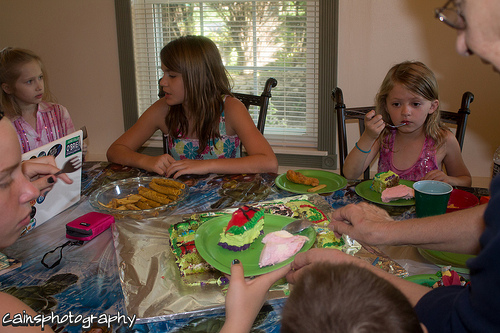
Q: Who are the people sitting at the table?
A: Young children.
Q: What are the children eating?
A: Cake.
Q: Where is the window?
A: Behind a girl with long hair.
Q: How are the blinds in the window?
A: Open.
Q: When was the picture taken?
A: During the daytime.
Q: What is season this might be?
A: Summer.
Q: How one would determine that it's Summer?
A: By the way the children are dressed.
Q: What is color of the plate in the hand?
A: Green.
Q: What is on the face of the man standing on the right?
A: Glasses.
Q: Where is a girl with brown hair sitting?
A: In front of window.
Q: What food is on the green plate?
A: Cake.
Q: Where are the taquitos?
A: Clear plate.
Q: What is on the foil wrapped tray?
A: Cake.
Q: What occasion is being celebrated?
A: Birthday.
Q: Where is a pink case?
A: On table in front of computer.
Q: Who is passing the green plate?
A: Girl with blue nail polish.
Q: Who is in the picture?
A: A man and children.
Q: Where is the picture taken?
A: A dining room.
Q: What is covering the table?
A: A tablecloth.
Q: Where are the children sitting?
A: At a table.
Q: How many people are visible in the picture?
A: Six.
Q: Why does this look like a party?
A: There is a cake.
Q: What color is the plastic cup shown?
A: Green.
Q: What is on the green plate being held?
A: Cake and ice cream.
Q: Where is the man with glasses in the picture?
A: To the right.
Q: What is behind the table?
A: A window.